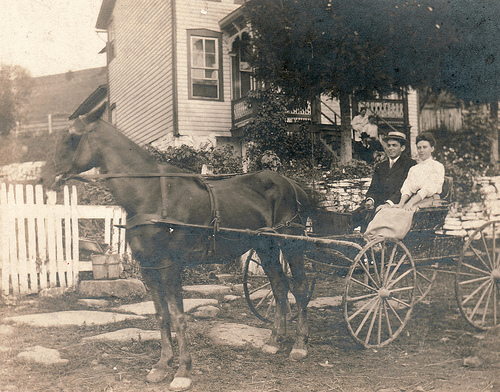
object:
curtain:
[192, 37, 217, 95]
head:
[36, 103, 108, 190]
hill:
[16, 57, 119, 144]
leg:
[258, 246, 289, 356]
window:
[190, 32, 217, 97]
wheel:
[345, 235, 420, 370]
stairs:
[278, 82, 415, 194]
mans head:
[316, 117, 488, 184]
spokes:
[462, 266, 480, 295]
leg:
[273, 207, 320, 364]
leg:
[247, 227, 291, 357]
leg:
[155, 241, 199, 390]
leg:
[128, 234, 174, 390]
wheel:
[450, 214, 497, 336]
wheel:
[238, 238, 326, 325]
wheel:
[400, 258, 448, 312]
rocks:
[11, 305, 171, 374]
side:
[107, 0, 175, 143]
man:
[347, 128, 415, 231]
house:
[97, 2, 257, 152]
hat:
[380, 130, 411, 147]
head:
[383, 135, 407, 161]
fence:
[1, 179, 128, 299]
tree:
[227, 6, 498, 171]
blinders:
[56, 114, 113, 146]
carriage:
[239, 126, 499, 363]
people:
[348, 104, 380, 155]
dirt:
[338, 353, 463, 387]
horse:
[36, 106, 335, 390]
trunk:
[341, 99, 352, 159]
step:
[316, 123, 370, 160]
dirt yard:
[2, 262, 483, 384]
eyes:
[57, 125, 80, 150]